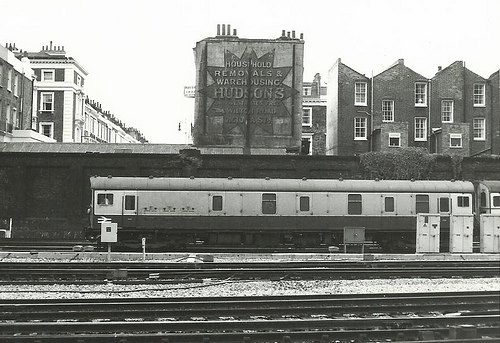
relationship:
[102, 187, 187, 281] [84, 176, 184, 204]
door with window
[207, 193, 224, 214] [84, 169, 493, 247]
window on train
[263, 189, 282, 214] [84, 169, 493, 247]
window on train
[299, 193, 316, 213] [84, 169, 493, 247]
window on train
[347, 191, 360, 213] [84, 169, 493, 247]
window on train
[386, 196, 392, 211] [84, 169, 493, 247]
window on train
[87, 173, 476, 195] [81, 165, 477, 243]
roof of train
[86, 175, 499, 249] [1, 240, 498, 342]
train on tracks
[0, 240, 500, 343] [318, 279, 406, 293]
ground on ground